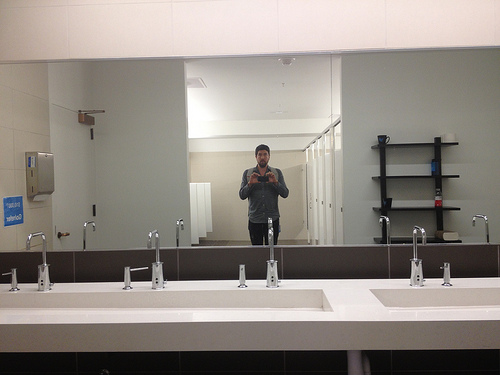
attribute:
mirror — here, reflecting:
[4, 52, 500, 254]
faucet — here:
[27, 232, 54, 284]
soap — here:
[3, 266, 18, 292]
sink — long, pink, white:
[0, 266, 500, 353]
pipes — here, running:
[9, 230, 467, 293]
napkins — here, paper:
[20, 143, 55, 210]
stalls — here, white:
[294, 132, 347, 240]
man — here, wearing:
[240, 143, 288, 239]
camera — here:
[253, 169, 280, 192]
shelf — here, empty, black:
[373, 127, 463, 235]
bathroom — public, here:
[1, 4, 493, 360]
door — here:
[299, 153, 314, 246]